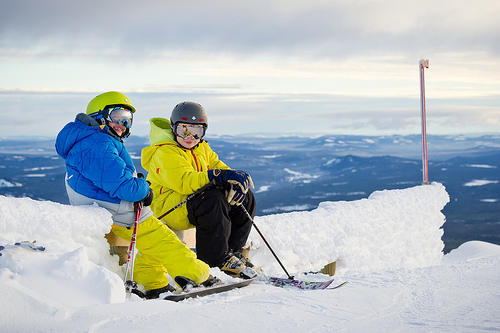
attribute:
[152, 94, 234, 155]
helmet — red, gray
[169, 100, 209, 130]
helmet — grey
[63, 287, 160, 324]
snow — white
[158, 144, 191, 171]
jacket — blue, white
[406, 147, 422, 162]
ground — yellow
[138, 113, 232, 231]
yellow jacket — ski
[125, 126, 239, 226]
jacket — blue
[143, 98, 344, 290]
skier — female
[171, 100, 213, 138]
helmet — grey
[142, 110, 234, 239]
jacket — yellow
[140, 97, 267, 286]
skier — female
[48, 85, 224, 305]
skier — female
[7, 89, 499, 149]
mountains — distant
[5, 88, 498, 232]
mountain range — distant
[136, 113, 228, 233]
jacket — yellow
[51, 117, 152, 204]
jacket — blue, ski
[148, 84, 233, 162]
helmet — gray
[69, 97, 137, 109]
helmet — green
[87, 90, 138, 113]
helmet — yellow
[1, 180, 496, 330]
slope — snowy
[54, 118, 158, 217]
jacket — blue, ski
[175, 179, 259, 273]
pants — black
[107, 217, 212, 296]
pants — yellow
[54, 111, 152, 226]
jacket — blue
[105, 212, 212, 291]
pants — bright